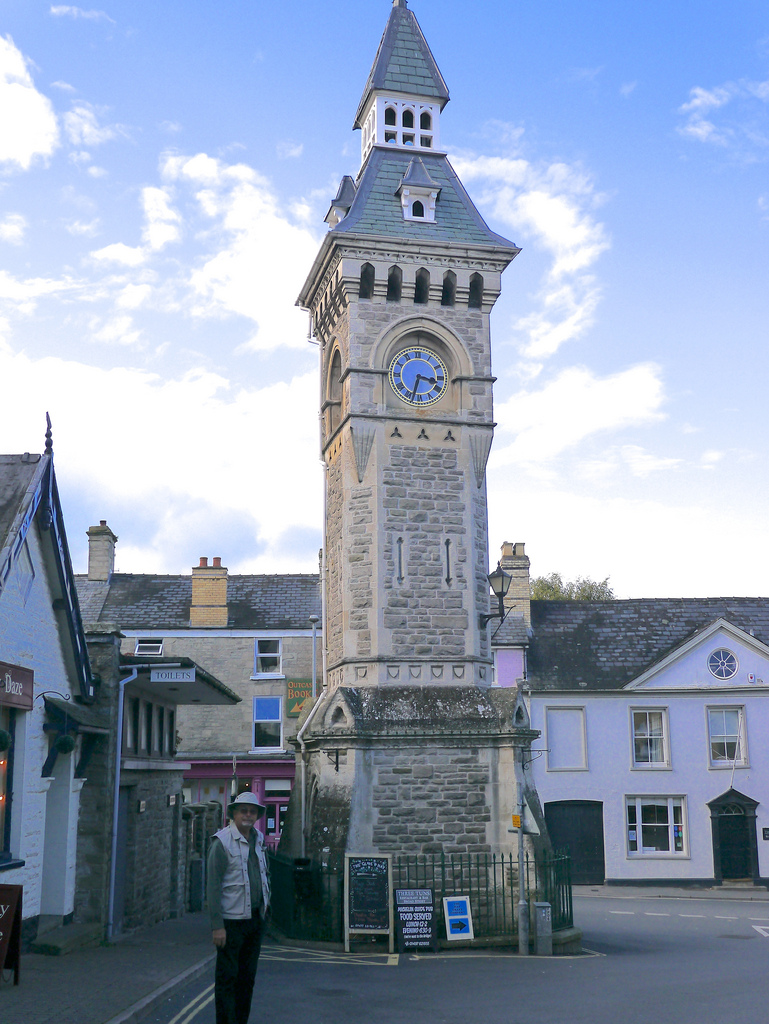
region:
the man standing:
[193, 786, 302, 1011]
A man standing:
[193, 791, 294, 1019]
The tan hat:
[222, 790, 269, 810]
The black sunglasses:
[233, 805, 268, 821]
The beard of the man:
[232, 815, 263, 829]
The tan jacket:
[202, 824, 282, 921]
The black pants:
[210, 912, 274, 1022]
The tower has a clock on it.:
[291, 1, 543, 953]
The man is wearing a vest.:
[184, 785, 280, 1022]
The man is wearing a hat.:
[189, 789, 293, 1020]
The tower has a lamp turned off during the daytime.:
[485, 566, 511, 623]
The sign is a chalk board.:
[334, 850, 396, 958]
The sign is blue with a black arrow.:
[436, 888, 485, 958]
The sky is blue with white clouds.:
[3, 4, 759, 597]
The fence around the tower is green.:
[264, 849, 577, 948]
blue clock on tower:
[384, 336, 449, 411]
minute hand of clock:
[403, 370, 424, 400]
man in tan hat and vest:
[197, 776, 277, 1014]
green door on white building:
[704, 782, 765, 891]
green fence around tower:
[264, 839, 577, 934]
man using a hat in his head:
[218, 790, 271, 827]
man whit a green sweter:
[211, 791, 288, 920]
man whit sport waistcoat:
[209, 830, 272, 914]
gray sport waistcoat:
[220, 830, 274, 905]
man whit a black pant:
[210, 794, 263, 1002]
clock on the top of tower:
[400, 338, 443, 398]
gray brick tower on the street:
[335, 251, 496, 666]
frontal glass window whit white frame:
[631, 708, 665, 770]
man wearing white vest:
[213, 775, 283, 1016]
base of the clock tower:
[287, 720, 531, 940]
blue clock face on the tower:
[392, 347, 446, 404]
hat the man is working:
[227, 792, 266, 808]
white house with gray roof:
[528, 595, 767, 904]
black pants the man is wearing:
[217, 925, 267, 1022]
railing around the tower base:
[279, 824, 582, 949]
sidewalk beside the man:
[45, 896, 239, 1020]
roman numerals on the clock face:
[383, 340, 447, 398]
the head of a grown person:
[206, 770, 274, 844]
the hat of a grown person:
[226, 785, 272, 815]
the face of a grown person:
[221, 796, 262, 837]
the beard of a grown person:
[228, 818, 258, 831]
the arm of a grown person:
[166, 821, 256, 966]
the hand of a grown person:
[191, 924, 241, 954]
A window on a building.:
[358, 260, 376, 299]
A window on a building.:
[617, 787, 694, 860]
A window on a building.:
[616, 695, 675, 776]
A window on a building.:
[710, 701, 747, 760]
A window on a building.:
[546, 696, 586, 765]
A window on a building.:
[254, 693, 281, 750]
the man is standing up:
[207, 790, 269, 1022]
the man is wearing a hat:
[205, 790, 273, 1021]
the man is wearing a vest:
[205, 790, 270, 1022]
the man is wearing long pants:
[207, 793, 271, 1021]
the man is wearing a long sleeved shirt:
[205, 790, 272, 1022]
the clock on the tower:
[264, 0, 573, 950]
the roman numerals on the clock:
[386, 346, 449, 407]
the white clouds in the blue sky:
[1, 0, 767, 604]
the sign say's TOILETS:
[149, 668, 197, 683]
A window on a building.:
[243, 688, 277, 745]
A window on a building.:
[248, 638, 276, 678]